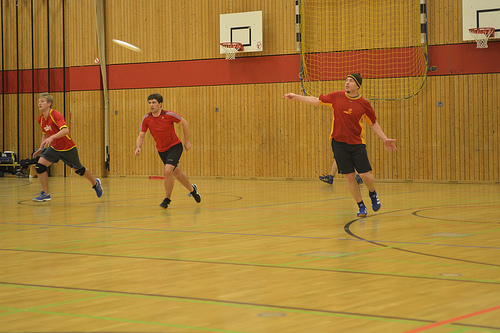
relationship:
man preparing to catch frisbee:
[285, 70, 398, 221] [96, 18, 165, 61]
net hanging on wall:
[294, 0, 428, 102] [190, 6, 285, 170]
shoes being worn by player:
[152, 195, 203, 210] [128, 87, 208, 212]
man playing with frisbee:
[285, 70, 398, 221] [104, 28, 143, 59]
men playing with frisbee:
[127, 86, 205, 208] [104, 28, 143, 59]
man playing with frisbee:
[24, 94, 107, 204] [104, 28, 143, 59]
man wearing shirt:
[285, 66, 397, 221] [312, 87, 377, 144]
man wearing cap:
[285, 66, 397, 221] [346, 72, 364, 87]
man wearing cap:
[285, 70, 398, 221] [346, 72, 364, 87]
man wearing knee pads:
[24, 94, 107, 204] [29, 158, 85, 177]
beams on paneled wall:
[15, 10, 106, 111] [0, 0, 500, 180]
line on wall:
[3, 36, 498, 93] [457, 95, 487, 170]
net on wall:
[294, 0, 428, 102] [119, 59, 494, 180]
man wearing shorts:
[285, 70, 398, 221] [330, 140, 373, 173]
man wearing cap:
[285, 70, 398, 221] [342, 64, 413, 105]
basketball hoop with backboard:
[219, 41, 242, 61] [203, 0, 284, 40]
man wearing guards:
[24, 94, 107, 204] [33, 160, 49, 176]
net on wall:
[294, 4, 428, 106] [4, 2, 494, 185]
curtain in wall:
[91, 1, 108, 174] [64, 0, 147, 177]